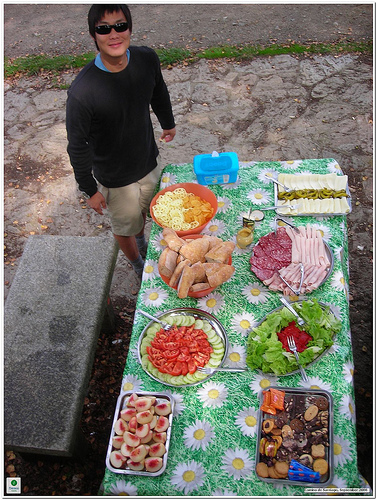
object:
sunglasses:
[93, 21, 131, 35]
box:
[193, 151, 239, 185]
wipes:
[212, 150, 218, 157]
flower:
[256, 166, 279, 185]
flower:
[247, 186, 272, 206]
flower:
[240, 281, 270, 305]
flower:
[196, 291, 225, 315]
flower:
[229, 310, 257, 338]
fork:
[199, 367, 248, 374]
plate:
[137, 307, 229, 389]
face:
[94, 11, 130, 58]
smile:
[95, 28, 132, 56]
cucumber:
[173, 314, 183, 326]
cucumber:
[186, 315, 195, 327]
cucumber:
[146, 326, 156, 338]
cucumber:
[210, 336, 221, 345]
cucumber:
[203, 320, 212, 333]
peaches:
[110, 393, 173, 472]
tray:
[104, 389, 175, 476]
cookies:
[63, 3, 177, 273]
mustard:
[236, 217, 255, 248]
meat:
[250, 227, 292, 281]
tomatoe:
[147, 323, 214, 376]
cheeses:
[277, 198, 349, 213]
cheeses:
[278, 172, 348, 191]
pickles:
[279, 187, 349, 205]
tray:
[273, 172, 352, 216]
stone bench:
[6, 232, 118, 453]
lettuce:
[247, 299, 340, 375]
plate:
[256, 299, 337, 376]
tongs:
[279, 262, 308, 295]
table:
[99, 158, 360, 496]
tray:
[253, 226, 335, 288]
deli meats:
[250, 224, 330, 296]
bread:
[159, 229, 235, 299]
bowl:
[158, 234, 231, 298]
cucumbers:
[140, 315, 225, 385]